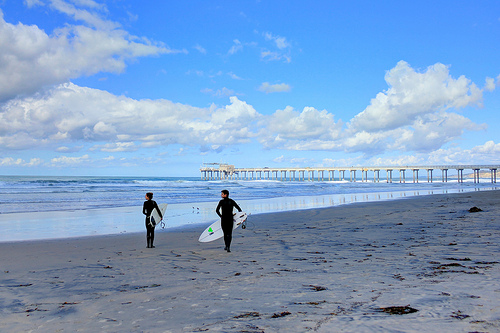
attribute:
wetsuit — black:
[216, 202, 237, 246]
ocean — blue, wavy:
[0, 175, 500, 242]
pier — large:
[193, 157, 498, 187]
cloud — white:
[2, 58, 477, 151]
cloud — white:
[1, 7, 180, 101]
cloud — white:
[310, 136, 499, 188]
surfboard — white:
[197, 222, 224, 259]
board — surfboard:
[193, 212, 263, 244]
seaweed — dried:
[379, 305, 417, 314]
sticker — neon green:
[207, 223, 212, 238]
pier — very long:
[199, 164, 498, 183]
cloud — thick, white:
[340, 60, 494, 135]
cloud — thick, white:
[206, 74, 288, 168]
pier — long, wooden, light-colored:
[198, 161, 498, 185]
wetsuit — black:
[214, 197, 246, 257]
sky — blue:
[0, 2, 498, 183]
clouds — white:
[346, 57, 493, 139]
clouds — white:
[255, 102, 349, 164]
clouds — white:
[6, 81, 251, 154]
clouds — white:
[3, 1, 187, 94]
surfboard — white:
[197, 205, 248, 245]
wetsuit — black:
[142, 200, 157, 245]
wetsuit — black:
[140, 199, 160, 251]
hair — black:
[218, 187, 229, 199]